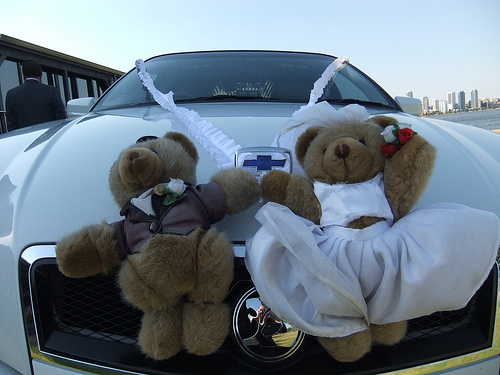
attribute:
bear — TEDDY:
[52, 130, 258, 357]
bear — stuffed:
[73, 101, 279, 323]